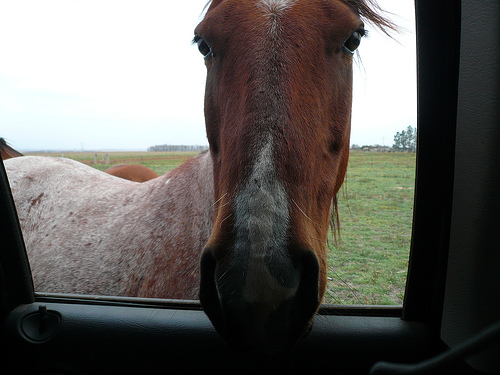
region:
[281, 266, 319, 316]
nose of a horse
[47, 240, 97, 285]
stomach of a horse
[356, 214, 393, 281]
part of a ground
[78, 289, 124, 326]
edge of a window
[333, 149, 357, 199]
jaw of a horse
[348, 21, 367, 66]
left eye of a horse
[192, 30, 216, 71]
right eye of a horse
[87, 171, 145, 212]
back of a horse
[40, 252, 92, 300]
stomach of a horse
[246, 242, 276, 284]
white part on the horse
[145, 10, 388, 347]
a horse head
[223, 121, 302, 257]
grey spot on the head of a horse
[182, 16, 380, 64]
two eyes on a horse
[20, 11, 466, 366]
a horse looking in a car window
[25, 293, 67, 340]
lock on a car door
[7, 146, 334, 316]
horse with grey hair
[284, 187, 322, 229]
a grey whisker on the horse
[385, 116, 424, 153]
green trees in the distance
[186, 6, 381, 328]
a brown horse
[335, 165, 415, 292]
field of green grass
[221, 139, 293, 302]
The hair around the horse's nose is white.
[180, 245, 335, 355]
The horse's nose is black.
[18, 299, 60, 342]
The car door is locked.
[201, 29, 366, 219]
The horse has a brown face.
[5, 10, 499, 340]
The horse is sticking it's head in a car window.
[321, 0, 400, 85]
The eyes are brown.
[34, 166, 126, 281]
The body is white.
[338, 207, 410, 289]
The grass is green.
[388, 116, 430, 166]
Small group of trees in the background.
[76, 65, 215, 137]
The sky is white.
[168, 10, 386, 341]
brown and white head of horse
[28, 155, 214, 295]
brown and white body of horse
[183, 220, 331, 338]
black nose of brown horse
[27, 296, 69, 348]
black door knob in car interior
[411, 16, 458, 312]
black door inside car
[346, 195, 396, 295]
green and brown grass in field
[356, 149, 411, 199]
green and brown grass in field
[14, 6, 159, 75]
white clouds in sky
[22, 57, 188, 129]
white clouds in blue sky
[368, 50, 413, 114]
white clouds in sky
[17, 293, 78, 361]
Black vehicle interior door lock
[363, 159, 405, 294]
Patchy green grass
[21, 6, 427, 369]
Horse sticking its nose inside a vehicle window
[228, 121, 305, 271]
White patch on brown horse's nose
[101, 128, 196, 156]
Line of trees off in the distance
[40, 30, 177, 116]
White sky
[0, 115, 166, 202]
Brown horse standing behind white spotted horse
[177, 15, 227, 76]
Brown horse's eye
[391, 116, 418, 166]
Tall trees behind horse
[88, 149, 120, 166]
Wood structure at edge of green grass